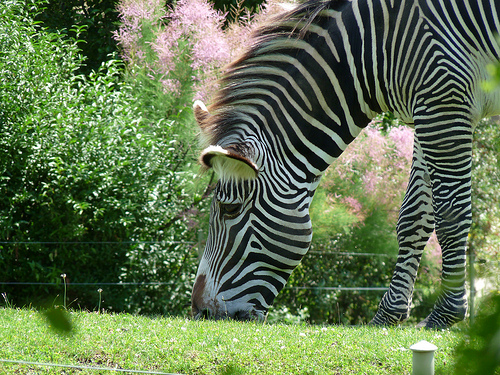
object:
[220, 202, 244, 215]
eye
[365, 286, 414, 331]
feet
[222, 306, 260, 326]
mouth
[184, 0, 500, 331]
zebra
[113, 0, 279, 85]
purple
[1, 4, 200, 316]
leaves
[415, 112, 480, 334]
leg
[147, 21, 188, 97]
flowers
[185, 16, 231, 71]
flowers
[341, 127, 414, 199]
flowers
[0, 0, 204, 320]
vegetation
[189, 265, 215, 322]
nose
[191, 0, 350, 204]
mane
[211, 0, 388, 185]
neck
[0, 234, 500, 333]
fence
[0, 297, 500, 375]
grass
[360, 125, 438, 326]
leg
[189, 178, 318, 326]
face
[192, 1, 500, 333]
fur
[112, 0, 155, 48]
flower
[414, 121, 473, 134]
stripes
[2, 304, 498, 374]
field